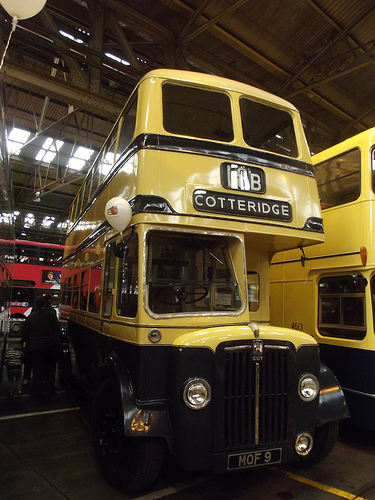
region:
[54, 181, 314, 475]
A parked double decker bus.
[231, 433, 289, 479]
A license tag in front of the bus.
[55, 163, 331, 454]
The bus is yellow and black.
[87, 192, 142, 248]
The bus has a balloon on it.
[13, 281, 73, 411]
Two men standing next to the bus.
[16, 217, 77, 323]
The bus in the background is red.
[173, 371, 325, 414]
The headlights on the bus.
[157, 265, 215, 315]
The steering wheel on the bus.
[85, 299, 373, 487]
Two double decker buses next to each other.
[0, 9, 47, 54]
A balloon on the top of ceiling.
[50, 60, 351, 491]
Big double decker style bus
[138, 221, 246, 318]
Windshield of a big bus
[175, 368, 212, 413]
Headlight of a big bus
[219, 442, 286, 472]
License plate of a big bus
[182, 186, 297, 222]
Sign on a big bus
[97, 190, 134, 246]
Balloon attached to a bus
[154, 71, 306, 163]
Top windows of a big bus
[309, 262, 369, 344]
Side windows of a bus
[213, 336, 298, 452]
Front grill of a bus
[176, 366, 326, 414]
Two head lights on a big bus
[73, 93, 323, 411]
yellow parked double decker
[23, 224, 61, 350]
red parked double decker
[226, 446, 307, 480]
black and silver license plate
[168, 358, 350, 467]
three front round headlights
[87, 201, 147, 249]
white balloon hanging from window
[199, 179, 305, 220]
text that says "Cotteridge"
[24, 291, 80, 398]
person in the shadow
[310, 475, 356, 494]
yellow lines on the ground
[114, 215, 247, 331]
small bus window L Shaped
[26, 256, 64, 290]
banner on side of doubledecker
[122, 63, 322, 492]
a double decker mini bus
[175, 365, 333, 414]
head light of th ebus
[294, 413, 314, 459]
front light of the bus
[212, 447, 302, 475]
number plate of the bus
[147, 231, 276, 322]
front driver window of bus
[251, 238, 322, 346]
a place to enter passengers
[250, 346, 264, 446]
a small middle line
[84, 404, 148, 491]
front wheel of the bus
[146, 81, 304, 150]
top window of the bus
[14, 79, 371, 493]
a big bus manufacturing factory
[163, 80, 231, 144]
window on top of bus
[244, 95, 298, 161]
window on top of bus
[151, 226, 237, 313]
window on top of bus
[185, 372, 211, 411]
head light on front of bus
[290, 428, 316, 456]
head light on front of bus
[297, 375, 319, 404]
head light on front of bus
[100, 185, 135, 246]
balloon on side of bus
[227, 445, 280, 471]
license plate on front of bus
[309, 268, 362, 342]
side window of bus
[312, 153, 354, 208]
side window of bus